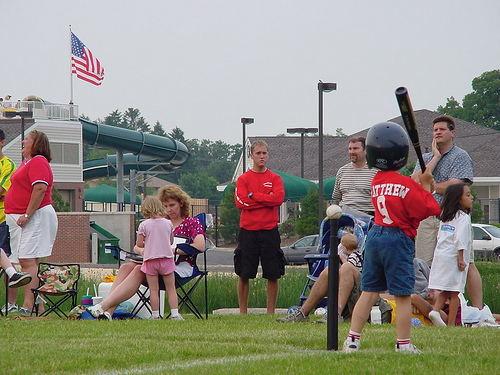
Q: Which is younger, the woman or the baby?
A: The baby is younger than the woman.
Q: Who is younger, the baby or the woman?
A: The baby is younger than the woman.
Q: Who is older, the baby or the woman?
A: The woman is older than the baby.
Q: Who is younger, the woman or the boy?
A: The boy is younger than the woman.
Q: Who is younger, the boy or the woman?
A: The boy is younger than the woman.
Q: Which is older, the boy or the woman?
A: The woman is older than the boy.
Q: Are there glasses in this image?
A: No, there are no glasses.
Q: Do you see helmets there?
A: Yes, there is a helmet.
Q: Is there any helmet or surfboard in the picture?
A: Yes, there is a helmet.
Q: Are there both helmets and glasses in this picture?
A: No, there is a helmet but no glasses.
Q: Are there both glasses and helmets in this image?
A: No, there is a helmet but no glasses.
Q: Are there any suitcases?
A: No, there are no suitcases.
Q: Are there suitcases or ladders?
A: No, there are no suitcases or ladders.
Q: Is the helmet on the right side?
A: Yes, the helmet is on the right of the image.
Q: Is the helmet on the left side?
A: No, the helmet is on the right of the image.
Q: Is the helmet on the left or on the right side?
A: The helmet is on the right of the image.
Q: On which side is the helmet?
A: The helmet is on the right of the image.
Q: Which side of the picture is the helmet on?
A: The helmet is on the right of the image.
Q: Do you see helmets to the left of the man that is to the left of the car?
A: Yes, there is a helmet to the left of the man.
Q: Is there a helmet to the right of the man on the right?
A: No, the helmet is to the left of the man.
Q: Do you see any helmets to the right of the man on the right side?
A: No, the helmet is to the left of the man.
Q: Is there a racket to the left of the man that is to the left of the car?
A: No, there is a helmet to the left of the man.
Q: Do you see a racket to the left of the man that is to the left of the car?
A: No, there is a helmet to the left of the man.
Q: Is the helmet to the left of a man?
A: Yes, the helmet is to the left of a man.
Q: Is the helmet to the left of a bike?
A: No, the helmet is to the left of a man.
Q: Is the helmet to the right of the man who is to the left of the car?
A: No, the helmet is to the left of the man.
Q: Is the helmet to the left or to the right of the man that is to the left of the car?
A: The helmet is to the left of the man.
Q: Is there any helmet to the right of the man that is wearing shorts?
A: Yes, there is a helmet to the right of the man.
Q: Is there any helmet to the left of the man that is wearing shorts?
A: No, the helmet is to the right of the man.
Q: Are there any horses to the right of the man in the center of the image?
A: No, there is a helmet to the right of the man.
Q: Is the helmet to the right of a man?
A: Yes, the helmet is to the right of a man.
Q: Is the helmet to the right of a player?
A: No, the helmet is to the right of a man.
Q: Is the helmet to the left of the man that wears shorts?
A: No, the helmet is to the right of the man.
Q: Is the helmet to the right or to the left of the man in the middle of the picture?
A: The helmet is to the right of the man.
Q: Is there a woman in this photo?
A: Yes, there is a woman.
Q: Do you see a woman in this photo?
A: Yes, there is a woman.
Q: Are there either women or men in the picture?
A: Yes, there is a woman.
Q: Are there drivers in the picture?
A: No, there are no drivers.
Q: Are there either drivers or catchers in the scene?
A: No, there are no drivers or catchers.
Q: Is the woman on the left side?
A: Yes, the woman is on the left of the image.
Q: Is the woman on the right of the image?
A: No, the woman is on the left of the image.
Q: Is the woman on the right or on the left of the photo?
A: The woman is on the left of the image.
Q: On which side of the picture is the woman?
A: The woman is on the left of the image.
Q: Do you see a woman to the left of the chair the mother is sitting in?
A: Yes, there is a woman to the left of the chair.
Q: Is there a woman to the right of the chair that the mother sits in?
A: No, the woman is to the left of the chair.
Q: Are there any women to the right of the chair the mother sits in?
A: No, the woman is to the left of the chair.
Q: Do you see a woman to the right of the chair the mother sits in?
A: No, the woman is to the left of the chair.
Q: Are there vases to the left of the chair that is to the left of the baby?
A: No, there is a woman to the left of the chair.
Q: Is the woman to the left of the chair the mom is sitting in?
A: Yes, the woman is to the left of the chair.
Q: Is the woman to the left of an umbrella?
A: No, the woman is to the left of the chair.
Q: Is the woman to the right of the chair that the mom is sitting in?
A: No, the woman is to the left of the chair.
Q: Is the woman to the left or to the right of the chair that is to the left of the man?
A: The woman is to the left of the chair.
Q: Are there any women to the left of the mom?
A: Yes, there is a woman to the left of the mom.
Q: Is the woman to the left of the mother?
A: Yes, the woman is to the left of the mother.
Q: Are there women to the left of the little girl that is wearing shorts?
A: Yes, there is a woman to the left of the girl.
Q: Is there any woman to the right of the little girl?
A: No, the woman is to the left of the girl.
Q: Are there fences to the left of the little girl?
A: No, there is a woman to the left of the girl.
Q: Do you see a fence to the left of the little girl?
A: No, there is a woman to the left of the girl.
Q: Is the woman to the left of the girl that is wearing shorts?
A: Yes, the woman is to the left of the girl.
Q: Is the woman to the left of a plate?
A: No, the woman is to the left of the girl.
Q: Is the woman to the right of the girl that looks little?
A: No, the woman is to the left of the girl.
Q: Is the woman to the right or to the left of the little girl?
A: The woman is to the left of the girl.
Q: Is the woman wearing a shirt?
A: Yes, the woman is wearing a shirt.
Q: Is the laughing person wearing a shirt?
A: Yes, the woman is wearing a shirt.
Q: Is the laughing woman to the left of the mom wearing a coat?
A: No, the woman is wearing a shirt.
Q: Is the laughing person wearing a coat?
A: No, the woman is wearing a shirt.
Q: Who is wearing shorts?
A: The woman is wearing shorts.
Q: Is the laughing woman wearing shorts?
A: Yes, the woman is wearing shorts.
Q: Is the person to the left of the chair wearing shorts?
A: Yes, the woman is wearing shorts.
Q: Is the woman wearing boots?
A: No, the woman is wearing shorts.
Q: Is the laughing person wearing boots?
A: No, the woman is wearing shorts.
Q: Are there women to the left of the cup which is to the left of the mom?
A: Yes, there is a woman to the left of the cup.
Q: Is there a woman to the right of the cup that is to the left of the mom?
A: No, the woman is to the left of the cup.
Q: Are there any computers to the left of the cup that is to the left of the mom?
A: No, there is a woman to the left of the cup.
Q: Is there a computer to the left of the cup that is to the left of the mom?
A: No, there is a woman to the left of the cup.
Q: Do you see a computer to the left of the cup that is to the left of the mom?
A: No, there is a woman to the left of the cup.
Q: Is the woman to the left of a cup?
A: Yes, the woman is to the left of a cup.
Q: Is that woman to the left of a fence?
A: No, the woman is to the left of a cup.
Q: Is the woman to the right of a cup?
A: No, the woman is to the left of a cup.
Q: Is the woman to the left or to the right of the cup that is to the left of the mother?
A: The woman is to the left of the cup.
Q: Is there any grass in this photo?
A: Yes, there is grass.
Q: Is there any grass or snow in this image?
A: Yes, there is grass.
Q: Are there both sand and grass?
A: No, there is grass but no sand.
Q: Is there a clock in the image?
A: No, there are no clocks.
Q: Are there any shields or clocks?
A: No, there are no clocks or shields.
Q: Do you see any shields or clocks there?
A: No, there are no clocks or shields.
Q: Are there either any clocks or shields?
A: No, there are no clocks or shields.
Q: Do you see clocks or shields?
A: No, there are no clocks or shields.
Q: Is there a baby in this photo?
A: Yes, there is a baby.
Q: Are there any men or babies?
A: Yes, there is a baby.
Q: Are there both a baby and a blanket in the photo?
A: No, there is a baby but no blankets.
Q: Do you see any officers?
A: No, there are no officers.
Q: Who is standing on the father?
A: The baby is standing on the father.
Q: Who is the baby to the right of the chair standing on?
A: The baby is standing on the father.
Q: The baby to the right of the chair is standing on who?
A: The baby is standing on the father.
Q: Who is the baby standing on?
A: The baby is standing on the father.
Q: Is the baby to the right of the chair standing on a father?
A: Yes, the baby is standing on a father.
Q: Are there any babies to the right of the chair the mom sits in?
A: Yes, there is a baby to the right of the chair.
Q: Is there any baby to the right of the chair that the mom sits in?
A: Yes, there is a baby to the right of the chair.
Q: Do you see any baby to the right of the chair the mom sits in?
A: Yes, there is a baby to the right of the chair.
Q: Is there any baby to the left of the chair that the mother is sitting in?
A: No, the baby is to the right of the chair.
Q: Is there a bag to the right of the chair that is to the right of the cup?
A: No, there is a baby to the right of the chair.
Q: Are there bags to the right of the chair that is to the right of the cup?
A: No, there is a baby to the right of the chair.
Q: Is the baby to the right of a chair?
A: Yes, the baby is to the right of a chair.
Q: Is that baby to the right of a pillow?
A: No, the baby is to the right of a chair.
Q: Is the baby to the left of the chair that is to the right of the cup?
A: No, the baby is to the right of the chair.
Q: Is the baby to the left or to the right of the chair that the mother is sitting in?
A: The baby is to the right of the chair.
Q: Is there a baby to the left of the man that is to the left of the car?
A: Yes, there is a baby to the left of the man.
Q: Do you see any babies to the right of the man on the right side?
A: No, the baby is to the left of the man.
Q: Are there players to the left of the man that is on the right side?
A: No, there is a baby to the left of the man.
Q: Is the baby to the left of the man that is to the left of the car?
A: Yes, the baby is to the left of the man.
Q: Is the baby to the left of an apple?
A: No, the baby is to the left of the man.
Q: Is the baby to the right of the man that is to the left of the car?
A: No, the baby is to the left of the man.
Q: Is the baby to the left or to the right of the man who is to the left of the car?
A: The baby is to the left of the man.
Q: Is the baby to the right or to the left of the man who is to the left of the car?
A: The baby is to the left of the man.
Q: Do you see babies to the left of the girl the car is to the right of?
A: Yes, there is a baby to the left of the girl.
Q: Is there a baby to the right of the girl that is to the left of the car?
A: No, the baby is to the left of the girl.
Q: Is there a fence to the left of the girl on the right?
A: No, there is a baby to the left of the girl.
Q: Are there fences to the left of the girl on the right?
A: No, there is a baby to the left of the girl.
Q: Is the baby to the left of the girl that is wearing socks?
A: Yes, the baby is to the left of the girl.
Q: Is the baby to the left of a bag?
A: No, the baby is to the left of the girl.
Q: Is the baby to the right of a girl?
A: No, the baby is to the left of a girl.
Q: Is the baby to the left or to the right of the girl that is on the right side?
A: The baby is to the left of the girl.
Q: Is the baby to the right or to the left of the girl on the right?
A: The baby is to the left of the girl.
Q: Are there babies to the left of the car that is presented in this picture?
A: Yes, there is a baby to the left of the car.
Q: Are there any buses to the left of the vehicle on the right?
A: No, there is a baby to the left of the car.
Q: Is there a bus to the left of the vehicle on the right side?
A: No, there is a baby to the left of the car.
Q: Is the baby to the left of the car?
A: Yes, the baby is to the left of the car.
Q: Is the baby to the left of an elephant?
A: No, the baby is to the left of the car.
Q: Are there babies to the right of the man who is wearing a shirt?
A: Yes, there is a baby to the right of the man.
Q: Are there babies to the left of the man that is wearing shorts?
A: No, the baby is to the right of the man.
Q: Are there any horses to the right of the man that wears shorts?
A: No, there is a baby to the right of the man.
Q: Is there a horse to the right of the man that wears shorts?
A: No, there is a baby to the right of the man.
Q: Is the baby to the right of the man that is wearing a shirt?
A: Yes, the baby is to the right of the man.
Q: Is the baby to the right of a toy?
A: No, the baby is to the right of the man.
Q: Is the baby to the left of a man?
A: No, the baby is to the right of a man.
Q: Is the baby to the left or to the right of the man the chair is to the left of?
A: The baby is to the right of the man.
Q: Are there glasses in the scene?
A: No, there are no glasses.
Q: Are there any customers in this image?
A: No, there are no customers.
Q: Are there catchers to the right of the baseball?
A: No, there is a man to the right of the baseball.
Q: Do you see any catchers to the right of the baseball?
A: No, there is a man to the right of the baseball.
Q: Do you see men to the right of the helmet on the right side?
A: Yes, there is a man to the right of the helmet.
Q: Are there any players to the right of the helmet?
A: No, there is a man to the right of the helmet.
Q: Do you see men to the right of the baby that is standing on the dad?
A: Yes, there is a man to the right of the baby.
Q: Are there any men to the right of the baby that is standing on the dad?
A: Yes, there is a man to the right of the baby.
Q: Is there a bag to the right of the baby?
A: No, there is a man to the right of the baby.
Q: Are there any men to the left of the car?
A: Yes, there is a man to the left of the car.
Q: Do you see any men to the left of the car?
A: Yes, there is a man to the left of the car.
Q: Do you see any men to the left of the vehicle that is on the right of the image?
A: Yes, there is a man to the left of the car.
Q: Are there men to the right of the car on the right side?
A: No, the man is to the left of the car.